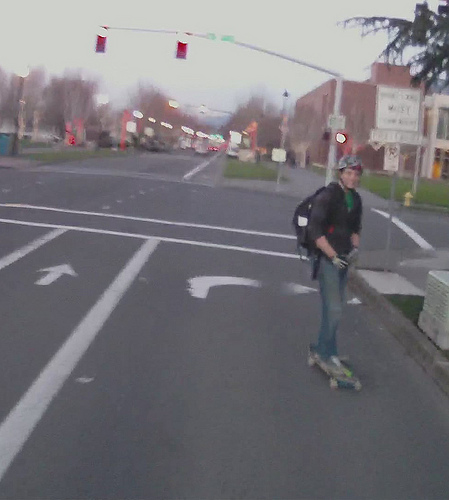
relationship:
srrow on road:
[30, 235, 102, 294] [0, 248, 448, 499]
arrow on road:
[31, 254, 89, 304] [0, 248, 448, 499]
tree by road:
[379, 17, 440, 239] [0, 248, 448, 499]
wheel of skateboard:
[324, 377, 342, 400] [279, 326, 371, 431]